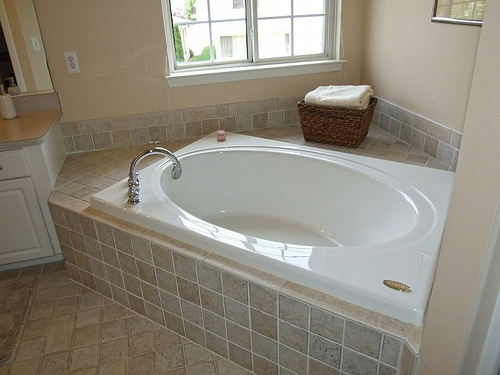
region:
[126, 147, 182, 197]
a silver faucet of a tub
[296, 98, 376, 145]
the brown wicket basket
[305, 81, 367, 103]
the white folded towel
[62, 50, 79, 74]
the white electrical socket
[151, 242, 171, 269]
the tan and brown bathroom tile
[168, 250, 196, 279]
the tan and brown bathroom tile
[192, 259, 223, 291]
the tan and brown bathroom tile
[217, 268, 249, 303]
the tan and brown bathroom tile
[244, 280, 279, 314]
the tan and brown bathroom tile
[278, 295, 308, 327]
the tan and brown bathroom tile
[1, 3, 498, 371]
Bathroom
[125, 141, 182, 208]
Faucet for the bath tub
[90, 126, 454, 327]
Rectangular shaped bath tub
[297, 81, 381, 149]
Basket of towels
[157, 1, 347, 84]
Panel of windows next to the bath tub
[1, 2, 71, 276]
Dresser with a mirror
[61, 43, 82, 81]
Plug port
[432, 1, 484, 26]
Compartment for bath products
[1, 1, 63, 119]
Mirror on top of the dresser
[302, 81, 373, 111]
Several white towels in the basket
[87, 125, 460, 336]
white bathtub in bathroom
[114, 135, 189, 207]
metal fauce in bathtub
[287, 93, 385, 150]
brown wicker basket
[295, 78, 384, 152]
white towels in wicker basket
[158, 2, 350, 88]
white framed window in bathroom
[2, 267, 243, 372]
tan tiled floors in bathroom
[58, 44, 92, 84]
white wall outlet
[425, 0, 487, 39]
silver framed mirror on wall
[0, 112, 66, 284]
bathroom counter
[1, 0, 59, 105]
mirror on wall over counter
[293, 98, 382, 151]
Wicker basket on tub shelf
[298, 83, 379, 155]
Folded towels in basket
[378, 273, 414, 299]
Bathtub manufacturer identification logo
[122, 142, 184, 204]
Metal faucet for bathtub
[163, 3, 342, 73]
Bathroom wall window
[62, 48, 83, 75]
Electric outlet on bathroom wall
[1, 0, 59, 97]
Mirror mounted on bathroom wall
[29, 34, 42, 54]
Electric light switch reflection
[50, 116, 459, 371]
Tile lining of bathtub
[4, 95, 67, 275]
Wooden vanity in bathroom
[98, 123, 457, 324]
a bathtub in the corner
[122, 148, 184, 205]
silver faucet on the tub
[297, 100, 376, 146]
brown wicker basket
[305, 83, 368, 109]
white folded towels in a wicker basket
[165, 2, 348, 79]
window over the tub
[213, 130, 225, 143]
pink bottle on the tub's edge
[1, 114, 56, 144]
bathroom counter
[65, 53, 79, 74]
electrical outlet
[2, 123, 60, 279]
white cabinets under the counter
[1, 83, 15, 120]
white soap dispenser on the counter